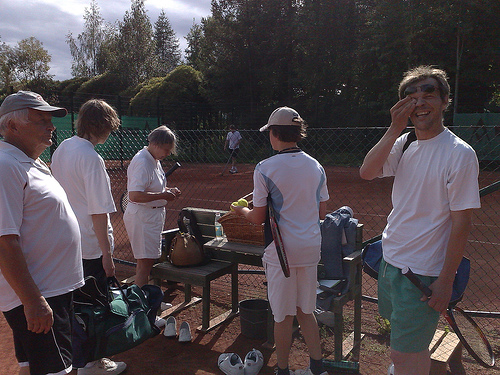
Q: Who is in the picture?
A: Men and women.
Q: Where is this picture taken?
A: A tennis court.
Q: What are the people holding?
A: Tennis rackets.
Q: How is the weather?
A: Clear.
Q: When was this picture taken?
A: Daytime.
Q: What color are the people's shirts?
A: White.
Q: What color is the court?
A: Brown.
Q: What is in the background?
A: Trees.